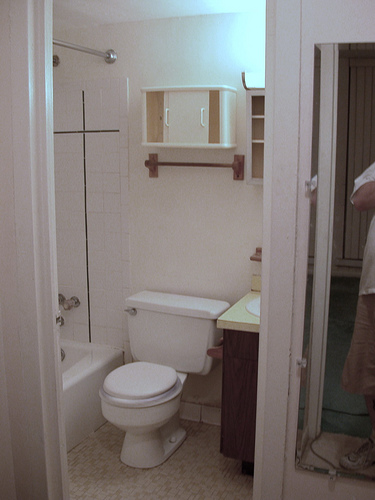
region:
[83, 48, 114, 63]
shower rod made out of iron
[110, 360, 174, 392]
stool lid closed down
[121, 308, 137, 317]
handle on stool to flush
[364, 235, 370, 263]
person wearing a white shirt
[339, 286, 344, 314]
carpet on the floor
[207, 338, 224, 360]
tissue holder on the side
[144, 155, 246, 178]
towel rack on the wall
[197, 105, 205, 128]
handles on the door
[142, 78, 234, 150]
white cabinet on the wall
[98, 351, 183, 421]
the toilet is white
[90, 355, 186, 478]
the toilet is white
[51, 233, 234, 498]
the bathroom is clean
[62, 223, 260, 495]
the bathroom is clean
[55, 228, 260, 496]
the bathroom is clean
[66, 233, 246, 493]
the bathroom is clean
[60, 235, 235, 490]
the bathroom is clean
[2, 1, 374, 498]
this is a bathroom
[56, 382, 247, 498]
tile on the floor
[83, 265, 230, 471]
this is a toilet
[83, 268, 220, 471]
the toilet is white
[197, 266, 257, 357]
corner of the sink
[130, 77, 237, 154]
cabinet in the bathroom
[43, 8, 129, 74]
a silver shower rod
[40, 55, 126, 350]
white tile in the showert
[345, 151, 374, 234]
this is an elbow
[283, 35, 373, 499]
mirror on the door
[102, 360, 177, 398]
a white plastic toilet seat lid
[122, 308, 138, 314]
a chrome flush handle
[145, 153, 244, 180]
a wooden towel bar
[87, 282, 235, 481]
white porcelain bathroom toilet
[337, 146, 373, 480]
right side portion of adult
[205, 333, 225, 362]
wooden toilet tissue holder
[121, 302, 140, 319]
silver toilet tank handle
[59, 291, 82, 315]
shower knob on wall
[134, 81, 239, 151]
white cabinet on wall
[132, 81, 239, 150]
white cabinet on wall over toilet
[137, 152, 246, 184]
wooden towel rack on wall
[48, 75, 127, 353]
white tile on shower wall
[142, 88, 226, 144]
white and brown gabiente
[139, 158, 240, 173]
long wooden bar